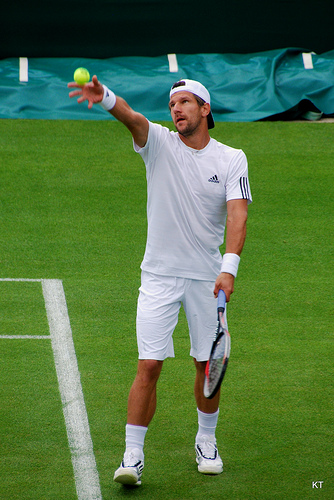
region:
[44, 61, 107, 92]
a yellow tennis ball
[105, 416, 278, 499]
white athletic sneakers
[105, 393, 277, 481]
white socks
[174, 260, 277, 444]
a tennis racket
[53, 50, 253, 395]
a man playing tennis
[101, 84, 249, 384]
a man holding a tennis racket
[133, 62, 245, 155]
a man wearing a white hat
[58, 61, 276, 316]
a man wearing white wrist bands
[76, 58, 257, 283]
a man wearing a white shirt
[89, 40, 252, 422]
a man wearing white shorts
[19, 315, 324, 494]
picture taken outdoors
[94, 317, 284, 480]
a man is a tennis player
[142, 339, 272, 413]
the man is holding a racket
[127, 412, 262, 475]
the man is wearing white socks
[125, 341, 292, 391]
the man is wearing shorts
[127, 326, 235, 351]
the shorts are white in color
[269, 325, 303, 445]
The grass is green.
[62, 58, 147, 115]
the tennis ball is yellow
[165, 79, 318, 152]
them man is wearing a hat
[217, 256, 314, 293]
the man is wearing wrist bands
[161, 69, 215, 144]
the head of a man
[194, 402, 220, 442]
a white sock on the man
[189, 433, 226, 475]
a white and blue shoe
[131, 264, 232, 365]
a white pair of shorts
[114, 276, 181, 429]
the leg of a man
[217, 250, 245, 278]
a white wristband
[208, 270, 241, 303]
the hand of a man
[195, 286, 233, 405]
a black and red racket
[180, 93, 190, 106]
the eye of a man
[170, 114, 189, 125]
the mouth of a man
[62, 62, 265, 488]
Man playing tennis on tennis court.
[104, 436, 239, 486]
Man wearing white and blue tennis shoes.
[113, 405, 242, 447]
Man wearing white socks.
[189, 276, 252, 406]
Man holding black and red tennis racket.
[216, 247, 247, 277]
Man wearing white band around wrist.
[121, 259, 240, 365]
Man dressed in white tennis shorts.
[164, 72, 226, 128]
Man wearing white cap turned backwards.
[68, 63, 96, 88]
Yellow tennis ball leaving man's hand.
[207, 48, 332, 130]
Green tarp and edge of tennis court.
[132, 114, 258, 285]
Man dressed in white shirt with blue accents.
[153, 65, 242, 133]
Man is wearing a white cap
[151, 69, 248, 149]
Man is wearing his cap backwards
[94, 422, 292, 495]
Man is wearing white tennis shoes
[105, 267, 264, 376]
Man is wearing white shorts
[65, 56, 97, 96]
Tennis ball is in the air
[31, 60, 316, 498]
Man is on a tennis court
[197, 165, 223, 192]
Man's shirt has a black logo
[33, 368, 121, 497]
Grass has a white line on it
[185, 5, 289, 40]
The background is dark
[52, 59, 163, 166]
Man's hand is extended out